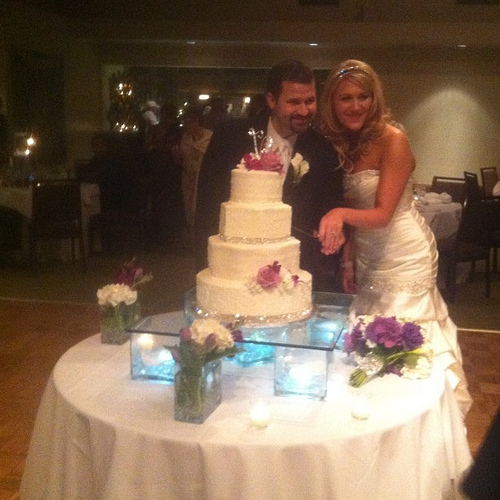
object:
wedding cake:
[194, 150, 315, 329]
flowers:
[363, 317, 404, 348]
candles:
[248, 398, 271, 431]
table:
[15, 310, 476, 499]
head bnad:
[323, 65, 374, 83]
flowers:
[242, 148, 282, 175]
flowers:
[256, 265, 281, 290]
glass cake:
[127, 303, 350, 400]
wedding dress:
[340, 170, 472, 438]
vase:
[169, 354, 223, 424]